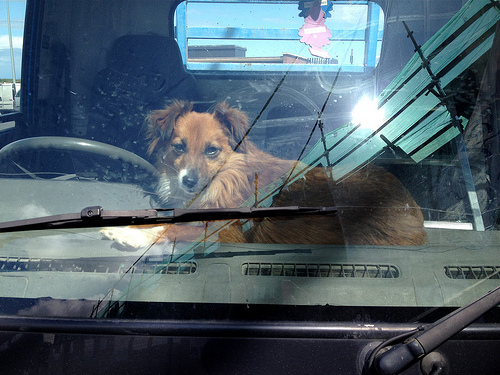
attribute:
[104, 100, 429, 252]
dog — brown, lying, sitting, white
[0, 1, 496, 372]
car — black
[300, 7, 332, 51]
air freshener — red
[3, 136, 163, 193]
steering wheel — grey, gray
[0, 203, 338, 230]
whipper — black, metal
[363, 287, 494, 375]
whipper — black, metal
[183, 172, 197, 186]
nose — black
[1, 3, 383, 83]
fence — blue, wooden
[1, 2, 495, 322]
windscreen — glass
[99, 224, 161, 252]
paw — white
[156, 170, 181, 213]
chest — white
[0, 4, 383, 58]
sky — blue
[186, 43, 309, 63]
object — wooden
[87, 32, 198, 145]
seat — black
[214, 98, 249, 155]
ear — flurry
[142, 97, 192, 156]
ear — flurry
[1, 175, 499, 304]
dashboard — gray